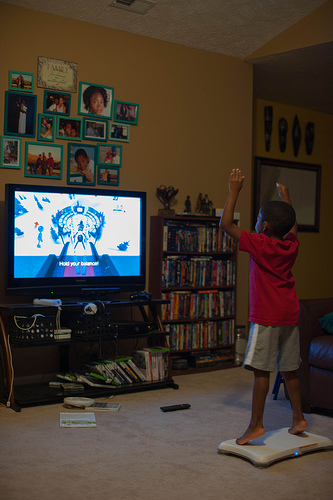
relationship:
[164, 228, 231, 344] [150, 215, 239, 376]
movie on shelf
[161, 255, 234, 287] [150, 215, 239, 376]
movies on shelf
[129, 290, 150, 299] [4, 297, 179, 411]
controller on tv stand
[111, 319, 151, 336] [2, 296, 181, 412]
vcr on shelf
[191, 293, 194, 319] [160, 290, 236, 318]
movie on shelf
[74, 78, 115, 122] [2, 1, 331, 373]
picture on wall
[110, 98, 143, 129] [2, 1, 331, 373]
picture on wall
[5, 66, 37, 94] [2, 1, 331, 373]
picture on wall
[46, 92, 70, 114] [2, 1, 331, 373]
picture on wall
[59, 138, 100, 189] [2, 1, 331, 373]
picture on wall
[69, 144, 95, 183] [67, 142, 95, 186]
picture in frame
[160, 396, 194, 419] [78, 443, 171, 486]
remote on floor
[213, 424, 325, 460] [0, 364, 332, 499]
wii platform on floor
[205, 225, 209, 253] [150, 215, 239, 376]
movie on shelf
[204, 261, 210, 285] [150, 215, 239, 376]
movie on shelf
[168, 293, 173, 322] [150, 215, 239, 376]
movie on shelf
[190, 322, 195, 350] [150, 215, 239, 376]
movie on shelf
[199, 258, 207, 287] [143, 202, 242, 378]
movie on shelf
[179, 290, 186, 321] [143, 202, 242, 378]
movie on shelf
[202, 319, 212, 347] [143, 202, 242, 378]
movie on shelf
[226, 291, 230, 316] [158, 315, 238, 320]
movie on shelf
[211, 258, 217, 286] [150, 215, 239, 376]
movie on shelf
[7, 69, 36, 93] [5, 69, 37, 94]
picture on frame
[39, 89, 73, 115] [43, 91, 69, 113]
picture on frame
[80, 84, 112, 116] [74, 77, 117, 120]
picture on frame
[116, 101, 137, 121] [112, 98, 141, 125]
picture on frame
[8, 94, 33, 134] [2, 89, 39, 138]
picture on frame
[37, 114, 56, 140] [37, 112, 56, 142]
picture on frame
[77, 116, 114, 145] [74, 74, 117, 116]
picture on frame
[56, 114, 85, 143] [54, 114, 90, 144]
picture on frame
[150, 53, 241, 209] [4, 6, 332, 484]
wall on building